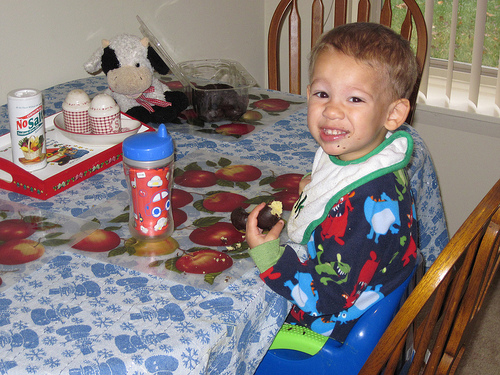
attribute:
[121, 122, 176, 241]
bottle — milk bottle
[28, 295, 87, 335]
snowman — blue 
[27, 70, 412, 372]
cloth — table cloth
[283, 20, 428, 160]
head — on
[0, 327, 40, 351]
snowman — blue